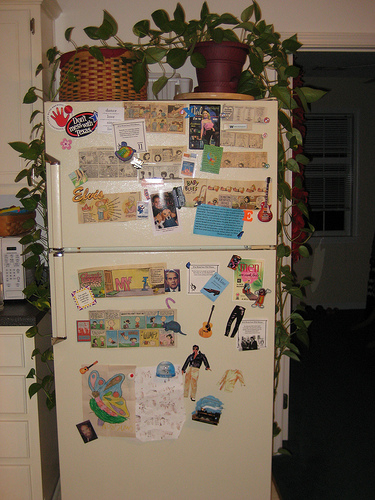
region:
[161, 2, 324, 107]
a leafy green houseplant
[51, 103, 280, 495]
a refrigerator covered in magnets, comics, photos and kids artwork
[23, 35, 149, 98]
a houseplant in a wicker basket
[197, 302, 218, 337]
a magnet of a yellow guitar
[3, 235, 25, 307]
a microwave ovens control panel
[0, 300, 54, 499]
a kitchen counter with drawers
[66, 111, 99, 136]
an oval magnet reading "don't mess with Texas"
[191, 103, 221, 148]
a snapshot of a woman wearing pink and black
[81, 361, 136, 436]
a coloring book page of a butterfly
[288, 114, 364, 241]
a window with blinds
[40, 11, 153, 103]
brown flower pot on top of fridge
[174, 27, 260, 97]
maroon flower pot on top of fridge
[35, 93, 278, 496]
fridge next to counter and microwave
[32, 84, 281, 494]
several magnets and pictures on fridge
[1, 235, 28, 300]
controls of a white microwave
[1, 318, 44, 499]
drawers of a white cabinet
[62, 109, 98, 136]
"don't mess with Texas" magnet on fridge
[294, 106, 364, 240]
window in dark back room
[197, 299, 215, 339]
guitar magnet on fridge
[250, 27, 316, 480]
flower handing down from fridge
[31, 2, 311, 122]
plants on top of a refridgerator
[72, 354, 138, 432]
a picture of a colorful butterfly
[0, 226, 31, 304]
the microwave is white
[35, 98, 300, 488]
the refrigerator is cream colored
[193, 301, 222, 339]
brown guitar magnet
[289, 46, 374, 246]
a white window in the background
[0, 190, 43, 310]
a brown basket on top of the microwave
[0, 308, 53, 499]
cabinet drawers are white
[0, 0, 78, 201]
cabinet is white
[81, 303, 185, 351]
a comic strip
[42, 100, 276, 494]
huge fridge near the counter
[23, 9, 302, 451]
a long potted plant atop the fridge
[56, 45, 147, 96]
a small wicker basket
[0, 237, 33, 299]
a white microwave on a counter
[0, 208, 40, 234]
small basket atop the microwave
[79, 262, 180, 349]
newspaper comics on the fridge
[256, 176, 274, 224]
guitar magnet on the fridge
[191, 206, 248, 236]
blue sheet of paper on fridge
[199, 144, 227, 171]
green sheet of paper on fridge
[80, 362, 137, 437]
butterfly coloring sheet on fridge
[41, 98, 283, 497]
Beige colored refrigerator and freezer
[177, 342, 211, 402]
Elvis magnet on refrigerator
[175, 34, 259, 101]
Plant pot on top of refrigerator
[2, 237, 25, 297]
Control panel on microwave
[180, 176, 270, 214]
Comic strip on door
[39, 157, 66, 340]
Refrigerator door handles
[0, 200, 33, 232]
Basket with markers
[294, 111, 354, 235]
Window in other room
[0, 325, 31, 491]
Four cabinet drawers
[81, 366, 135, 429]
Butterfly colored with crayons